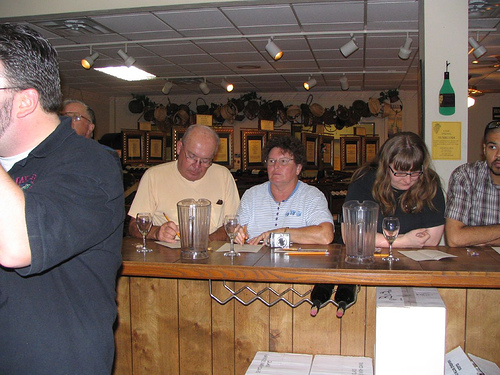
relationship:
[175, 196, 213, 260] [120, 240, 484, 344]
pitcher on table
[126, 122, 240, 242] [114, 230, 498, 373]
man sitting at bar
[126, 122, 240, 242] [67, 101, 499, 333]
man sitting at bar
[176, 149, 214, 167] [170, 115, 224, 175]
eye glasses on face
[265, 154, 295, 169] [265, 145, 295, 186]
eye glasses on face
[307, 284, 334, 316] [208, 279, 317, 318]
wine bottle placed on rack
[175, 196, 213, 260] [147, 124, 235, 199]
pitcher kept in front of man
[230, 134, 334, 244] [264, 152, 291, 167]
woman wearing spectacle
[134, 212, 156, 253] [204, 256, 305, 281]
wine glass kept on table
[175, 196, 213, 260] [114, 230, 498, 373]
pitcher on bar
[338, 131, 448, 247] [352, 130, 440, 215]
person has hair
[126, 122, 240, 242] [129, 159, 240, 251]
man wearing shirt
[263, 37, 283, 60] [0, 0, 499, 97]
light on ceiling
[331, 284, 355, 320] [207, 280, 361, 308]
wine bottle on rack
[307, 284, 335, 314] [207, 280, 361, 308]
wine bottle on rack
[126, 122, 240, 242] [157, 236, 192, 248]
man writing on paper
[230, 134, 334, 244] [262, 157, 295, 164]
woman wearing glasses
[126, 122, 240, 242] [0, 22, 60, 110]
man has hair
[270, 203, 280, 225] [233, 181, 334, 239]
buttons on shirt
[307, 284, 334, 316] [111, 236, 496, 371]
wine bottle under counter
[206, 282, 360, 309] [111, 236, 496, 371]
rack under counter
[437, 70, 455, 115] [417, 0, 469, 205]
wine bottle drawn on wall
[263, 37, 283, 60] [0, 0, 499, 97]
light in ceiling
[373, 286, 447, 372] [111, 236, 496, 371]
box under counter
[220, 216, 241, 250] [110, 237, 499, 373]
glass on table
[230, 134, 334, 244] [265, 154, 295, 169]
woman wearing eye glasses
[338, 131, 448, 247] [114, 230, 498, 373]
person leaning over bar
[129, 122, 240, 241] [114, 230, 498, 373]
man writing at bar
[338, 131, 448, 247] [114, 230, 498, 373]
person sitting at bar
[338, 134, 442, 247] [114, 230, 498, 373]
person sitting at bar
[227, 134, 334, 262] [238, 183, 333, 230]
woman wearing shirt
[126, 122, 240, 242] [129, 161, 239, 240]
man wearing shirt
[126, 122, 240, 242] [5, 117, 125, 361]
man wearing shirt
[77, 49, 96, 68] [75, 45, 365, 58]
light in line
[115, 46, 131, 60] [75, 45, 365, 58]
light in line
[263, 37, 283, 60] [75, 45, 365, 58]
light in line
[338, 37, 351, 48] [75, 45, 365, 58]
light in line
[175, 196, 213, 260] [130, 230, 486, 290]
pitcher on counter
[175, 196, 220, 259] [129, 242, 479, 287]
pitcher on counter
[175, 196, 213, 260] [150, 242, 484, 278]
pitcher on counter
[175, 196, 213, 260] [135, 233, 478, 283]
pitcher on counter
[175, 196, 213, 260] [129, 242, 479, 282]
pitcher on counter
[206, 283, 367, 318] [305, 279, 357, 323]
rack for wine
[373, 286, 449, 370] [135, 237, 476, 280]
box under counter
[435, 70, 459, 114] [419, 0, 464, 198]
cozy hanging on wall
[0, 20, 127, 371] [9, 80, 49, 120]
bartender has ear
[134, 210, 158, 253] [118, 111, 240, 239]
wine glass in front of man